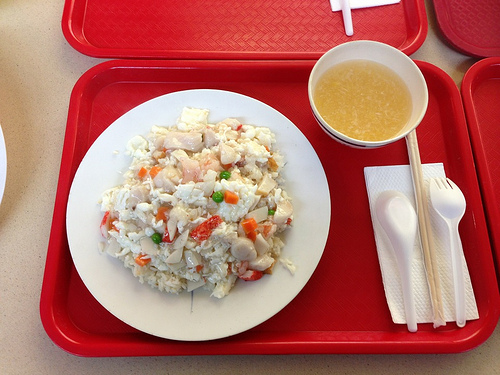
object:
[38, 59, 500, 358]
tray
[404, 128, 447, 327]
chop sticks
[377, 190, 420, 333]
spoon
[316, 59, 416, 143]
soup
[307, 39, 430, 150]
bowl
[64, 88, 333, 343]
plate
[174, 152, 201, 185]
chicken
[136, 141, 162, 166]
rice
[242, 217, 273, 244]
carrots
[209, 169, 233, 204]
peas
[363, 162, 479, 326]
napkin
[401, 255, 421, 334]
handle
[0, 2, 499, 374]
table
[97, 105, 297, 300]
meal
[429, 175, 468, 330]
fork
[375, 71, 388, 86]
particles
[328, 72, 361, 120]
broth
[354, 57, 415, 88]
inside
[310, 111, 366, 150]
line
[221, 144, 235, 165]
chunk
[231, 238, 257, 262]
scallop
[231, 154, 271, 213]
food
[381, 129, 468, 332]
utensils